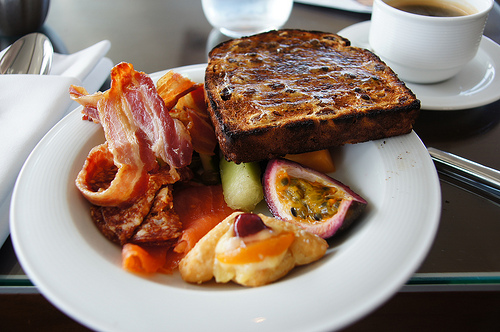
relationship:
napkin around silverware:
[5, 33, 111, 253] [7, 30, 52, 77]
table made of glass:
[2, 5, 496, 322] [410, 180, 497, 297]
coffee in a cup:
[384, 2, 476, 22] [364, 3, 492, 85]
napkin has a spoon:
[5, 33, 111, 253] [7, 30, 52, 77]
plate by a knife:
[8, 57, 445, 331] [427, 139, 498, 205]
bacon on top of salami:
[69, 60, 232, 208] [78, 164, 184, 247]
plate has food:
[15, 1, 499, 330] [67, 30, 421, 287]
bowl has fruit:
[8, 57, 445, 331] [221, 158, 367, 241]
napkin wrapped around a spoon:
[5, 33, 111, 253] [7, 30, 52, 77]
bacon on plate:
[69, 60, 232, 208] [8, 57, 445, 331]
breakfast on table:
[15, 1, 499, 330] [2, 5, 496, 322]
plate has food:
[8, 57, 445, 331] [67, 30, 421, 287]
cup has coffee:
[364, 3, 492, 85] [384, 2, 476, 22]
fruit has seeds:
[221, 158, 367, 241] [278, 173, 340, 224]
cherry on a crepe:
[233, 211, 265, 238] [183, 210, 329, 288]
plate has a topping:
[8, 57, 445, 331] [203, 30, 418, 162]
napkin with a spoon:
[5, 33, 111, 253] [7, 30, 52, 77]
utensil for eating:
[427, 139, 498, 205] [67, 30, 421, 287]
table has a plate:
[2, 5, 496, 322] [8, 57, 445, 331]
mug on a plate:
[364, 3, 492, 85] [335, 17, 498, 112]